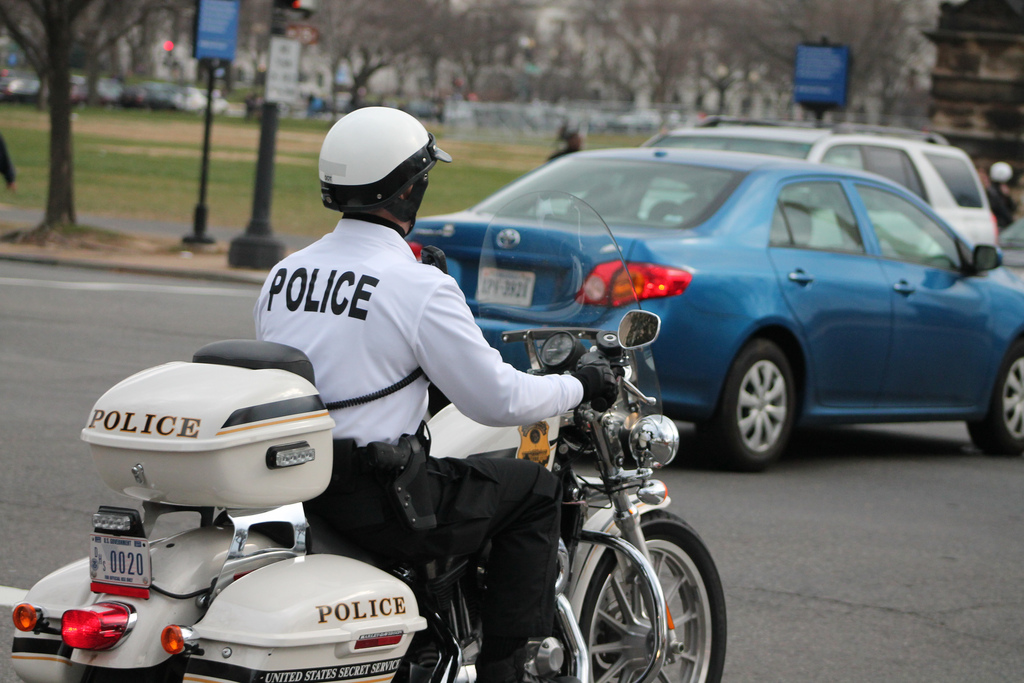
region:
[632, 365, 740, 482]
A person eating a orange.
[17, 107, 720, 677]
a policeman riding a white motorcycle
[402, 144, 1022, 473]
blue car with red taillights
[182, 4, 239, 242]
a blue sign on a black pole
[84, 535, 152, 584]
a white and blue license plate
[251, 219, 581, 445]
a white shirt with the word police written on it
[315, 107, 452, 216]
a white helmet with a black visor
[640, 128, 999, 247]
a silver SUV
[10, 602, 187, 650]
orange and red lights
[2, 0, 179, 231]
a tree with dead branches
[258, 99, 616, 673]
A cop on a motorcycle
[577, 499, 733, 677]
A tire on a motorcycle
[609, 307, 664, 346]
A mirror on a motorcycle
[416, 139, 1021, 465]
A blue car parked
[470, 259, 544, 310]
A license plate on a car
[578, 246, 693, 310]
A red tail light on a car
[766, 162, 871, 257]
A window on a car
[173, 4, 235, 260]
A sign near the street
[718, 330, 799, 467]
Black tire of a car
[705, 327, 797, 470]
Tire of a blue car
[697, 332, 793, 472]
Black tire of a blue car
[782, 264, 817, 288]
Handle of a car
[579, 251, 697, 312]
Tail light of a blue car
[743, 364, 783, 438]
Rim of a tire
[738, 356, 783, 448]
Rim of a black tire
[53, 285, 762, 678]
white and black police motorcycle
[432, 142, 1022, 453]
blue car on the street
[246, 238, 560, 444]
white shirt the man is wearing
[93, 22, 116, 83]
leaves on the tree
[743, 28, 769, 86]
leaves on the tree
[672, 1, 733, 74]
leaves on the tree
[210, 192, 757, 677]
a motorcycle ont he road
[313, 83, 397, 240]
a person wearing a helmet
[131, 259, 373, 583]
a perosn on a bike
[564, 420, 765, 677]
a tire on the bike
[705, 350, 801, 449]
a tire on the car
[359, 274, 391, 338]
a black letter on the shirt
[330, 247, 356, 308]
a black letter on the shirt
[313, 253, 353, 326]
a black letter on the shirt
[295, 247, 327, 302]
a black letter on the shirt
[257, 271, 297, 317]
a black letter on the shirt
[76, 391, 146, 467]
a black letter on the shirt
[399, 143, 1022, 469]
blue car driving on a road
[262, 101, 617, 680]
police officer in a white shirt and black pants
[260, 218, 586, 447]
police officer's white shirt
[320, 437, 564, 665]
police officer's black pants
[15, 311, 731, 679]
police officer's white motorcycle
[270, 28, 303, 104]
white sign hanging on a pole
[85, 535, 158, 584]
license plate on a mtorcycle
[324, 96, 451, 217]
police officer's black and white helmet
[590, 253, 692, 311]
red light on the back of a blue car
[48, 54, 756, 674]
cop on a bike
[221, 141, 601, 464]
cop wearing a white shirt